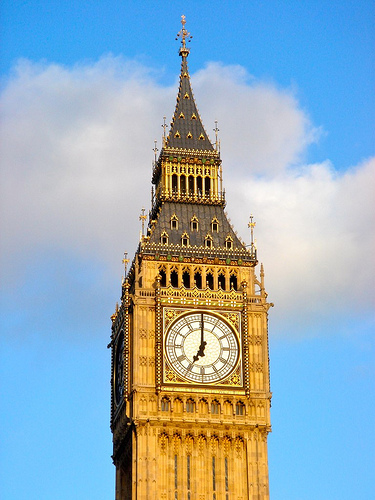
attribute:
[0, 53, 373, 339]
cloud — white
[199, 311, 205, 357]
hand — black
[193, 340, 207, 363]
hand — black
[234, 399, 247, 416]
arch — open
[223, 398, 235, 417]
arch — open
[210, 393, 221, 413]
arch — open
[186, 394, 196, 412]
arch — open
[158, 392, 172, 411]
arch — open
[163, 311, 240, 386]
clock — large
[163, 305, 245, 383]
clock — large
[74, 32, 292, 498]
clock tower — gothic, fancy, gold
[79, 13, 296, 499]
building — yellow, tall, old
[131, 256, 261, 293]
cornice design — gothic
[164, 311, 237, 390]
clock face — white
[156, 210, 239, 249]
windows — recessed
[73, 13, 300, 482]
clock tower — ornate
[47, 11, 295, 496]
old building — tall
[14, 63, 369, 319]
puffy clouds — white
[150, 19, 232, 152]
pointed roof — dark gray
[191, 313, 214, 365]
time — 7:00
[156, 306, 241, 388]
clock — brown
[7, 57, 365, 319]
cloud — white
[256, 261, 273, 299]
green decorations — brown